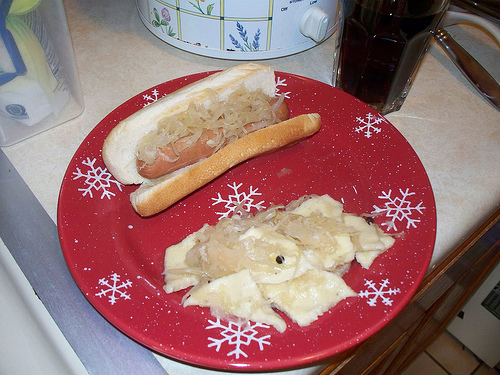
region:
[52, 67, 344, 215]
sauerkraut on a hot dog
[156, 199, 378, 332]
sauerkraut on cheese or ravioli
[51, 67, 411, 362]
dinner on a red plate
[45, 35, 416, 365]
red plate with white snow flakes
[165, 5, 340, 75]
crock pot dial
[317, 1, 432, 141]
glass of soda next to red plate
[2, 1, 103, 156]
plastic silverware in a canister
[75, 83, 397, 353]
hot dog on red plate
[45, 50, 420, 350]
hot dog and cheese on snow flake plate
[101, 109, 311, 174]
hot dog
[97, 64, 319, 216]
a hotdog with sauerkraut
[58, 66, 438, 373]
a red plate with a snowflake pattern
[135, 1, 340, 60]
the bottom of a crockpot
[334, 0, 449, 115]
a glass cup with a beverage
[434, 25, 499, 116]
the handle of a butterknife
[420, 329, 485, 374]
a floor tile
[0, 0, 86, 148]
a plastic container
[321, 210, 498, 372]
wooden cabinet doors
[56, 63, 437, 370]
a season themed plate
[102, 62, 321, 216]
a hotdog on a bun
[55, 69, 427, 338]
food on a red plate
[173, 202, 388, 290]
pasta on a red plate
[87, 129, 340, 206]
hot dog on a bun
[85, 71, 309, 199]
hot dog with sauerkraut on plate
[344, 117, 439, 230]
red plate with white snowflake design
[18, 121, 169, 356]
red plate is round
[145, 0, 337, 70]
bottom half of crock pot on table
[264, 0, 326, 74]
knobs to work the crock pot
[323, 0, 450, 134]
dark colored beverage in a glass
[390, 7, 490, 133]
part of a kitchen utensil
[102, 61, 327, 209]
hotdog is on bun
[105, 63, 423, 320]
plate has food on it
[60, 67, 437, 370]
plate is red and white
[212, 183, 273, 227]
plate has snowflakes on it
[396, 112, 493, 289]
plate is on the counter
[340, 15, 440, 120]
glass is near plate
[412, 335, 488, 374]
tile is on the floor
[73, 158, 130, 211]
stars on plate are white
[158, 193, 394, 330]
pasta is on the plate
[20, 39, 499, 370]
counter is under the plate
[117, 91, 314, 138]
sauerkraut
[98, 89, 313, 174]
hot dog on a bun topped with sauerkraut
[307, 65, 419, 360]
red plate with white snowflakes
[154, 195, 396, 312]
food on a plate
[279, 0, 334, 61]
dial on slow cooker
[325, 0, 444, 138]
glass full of cola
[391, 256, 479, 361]
front of cabinet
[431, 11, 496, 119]
metal utensil handle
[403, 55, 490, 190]
formica counter top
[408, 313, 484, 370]
kitchen floor tile